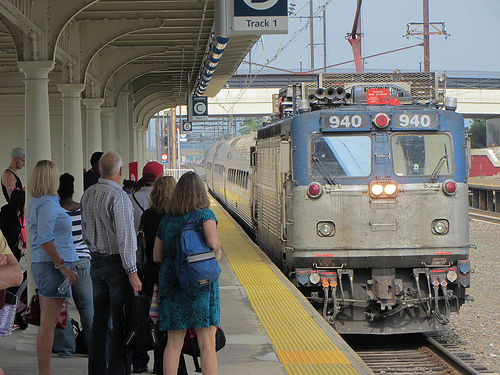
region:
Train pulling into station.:
[202, 73, 477, 338]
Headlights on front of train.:
[363, 176, 405, 204]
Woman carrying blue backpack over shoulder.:
[176, 208, 223, 294]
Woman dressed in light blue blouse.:
[18, 194, 80, 266]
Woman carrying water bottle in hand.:
[51, 269, 81, 297]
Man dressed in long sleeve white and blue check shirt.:
[81, 173, 148, 278]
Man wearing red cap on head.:
[141, 158, 166, 183]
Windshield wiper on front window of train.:
[424, 139, 457, 184]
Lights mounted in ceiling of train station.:
[191, 34, 232, 96]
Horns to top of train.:
[303, 78, 354, 109]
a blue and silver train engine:
[254, 86, 471, 345]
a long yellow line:
[201, 191, 352, 373]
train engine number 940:
[320, 113, 365, 131]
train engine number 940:
[393, 110, 434, 130]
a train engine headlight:
[368, 182, 397, 197]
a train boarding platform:
[10, 178, 376, 370]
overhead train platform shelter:
[0, 0, 292, 245]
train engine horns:
[313, 84, 347, 100]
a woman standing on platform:
[152, 173, 219, 373]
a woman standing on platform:
[138, 171, 178, 360]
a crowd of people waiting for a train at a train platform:
[4, 50, 497, 374]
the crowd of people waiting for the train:
[0, 138, 290, 371]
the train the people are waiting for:
[205, 101, 478, 351]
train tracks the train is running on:
[340, 333, 491, 373]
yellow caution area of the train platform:
[212, 198, 374, 373]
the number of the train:
[322, 106, 444, 133]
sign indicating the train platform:
[188, 92, 212, 122]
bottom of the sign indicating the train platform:
[215, 0, 290, 35]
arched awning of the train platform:
[2, 3, 212, 168]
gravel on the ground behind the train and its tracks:
[470, 225, 497, 350]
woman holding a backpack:
[150, 170, 221, 370]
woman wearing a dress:
[145, 170, 230, 365]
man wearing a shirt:
[72, 140, 154, 370]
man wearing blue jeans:
[76, 140, 139, 371]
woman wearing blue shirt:
[16, 155, 86, 372]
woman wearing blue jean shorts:
[18, 151, 73, 371]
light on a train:
[350, 165, 406, 220]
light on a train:
[361, 108, 398, 145]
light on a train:
[300, 175, 330, 211]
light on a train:
[440, 173, 465, 203]